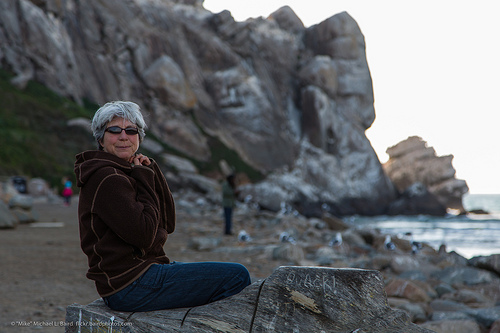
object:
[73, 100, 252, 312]
woman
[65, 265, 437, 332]
rock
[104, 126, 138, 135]
sunglasses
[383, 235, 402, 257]
seagull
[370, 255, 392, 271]
rock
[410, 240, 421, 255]
seagull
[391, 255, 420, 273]
rock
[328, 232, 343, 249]
seagull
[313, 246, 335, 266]
rock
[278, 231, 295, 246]
seagull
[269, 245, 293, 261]
rock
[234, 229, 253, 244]
seagull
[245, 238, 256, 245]
rock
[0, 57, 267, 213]
slope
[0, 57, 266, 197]
vegetation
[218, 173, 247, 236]
person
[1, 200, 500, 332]
beach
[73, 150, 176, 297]
hoodie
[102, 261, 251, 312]
pair of jeans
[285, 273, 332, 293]
"quack"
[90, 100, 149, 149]
hair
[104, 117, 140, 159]
face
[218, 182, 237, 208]
green jacket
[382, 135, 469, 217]
big rock formatons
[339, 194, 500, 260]
water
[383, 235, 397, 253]
bird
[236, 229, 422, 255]
ducks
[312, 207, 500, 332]
shoreline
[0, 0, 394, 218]
large rock formation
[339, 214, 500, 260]
shore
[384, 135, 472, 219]
large rock formation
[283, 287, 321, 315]
vandalized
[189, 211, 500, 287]
rocky shore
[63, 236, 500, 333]
rocky shore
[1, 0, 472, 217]
rock landscape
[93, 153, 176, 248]
arms folded